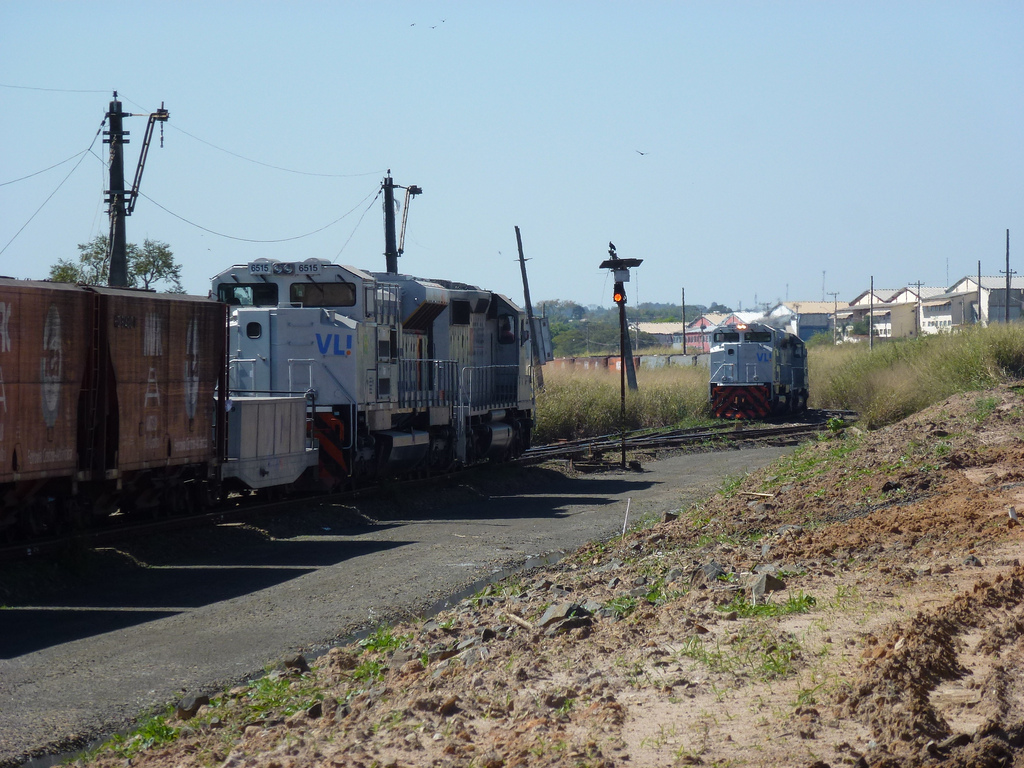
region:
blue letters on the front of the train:
[310, 325, 353, 360]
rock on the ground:
[510, 578, 612, 656]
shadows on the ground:
[124, 544, 309, 598]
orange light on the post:
[608, 282, 625, 317]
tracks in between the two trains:
[614, 417, 726, 450]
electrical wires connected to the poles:
[84, 79, 424, 247]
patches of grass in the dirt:
[731, 591, 824, 637]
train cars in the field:
[642, 350, 706, 373]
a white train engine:
[214, 261, 531, 493]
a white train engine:
[708, 321, 795, 419]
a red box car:
[5, 277, 220, 537]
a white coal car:
[223, 393, 318, 496]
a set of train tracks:
[495, 406, 846, 468]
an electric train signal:
[597, 241, 640, 470]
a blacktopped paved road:
[0, 441, 808, 759]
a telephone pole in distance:
[103, 92, 133, 280]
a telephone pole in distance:
[379, 171, 403, 276]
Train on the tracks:
[694, 293, 813, 423]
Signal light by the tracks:
[601, 243, 649, 472]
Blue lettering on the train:
[298, 322, 363, 364]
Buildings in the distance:
[623, 268, 1020, 376]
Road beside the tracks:
[5, 423, 859, 765]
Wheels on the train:
[2, 459, 225, 546]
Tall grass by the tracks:
[531, 319, 1019, 444]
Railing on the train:
[392, 358, 528, 415]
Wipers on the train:
[220, 265, 354, 303]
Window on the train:
[283, 271, 364, 317]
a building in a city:
[885, 280, 949, 339]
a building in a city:
[851, 283, 896, 341]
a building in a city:
[719, 302, 764, 329]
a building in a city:
[689, 310, 724, 349]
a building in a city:
[626, 308, 687, 357]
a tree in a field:
[30, 212, 185, 288]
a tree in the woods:
[538, 285, 586, 366]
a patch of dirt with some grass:
[259, 669, 389, 765]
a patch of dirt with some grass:
[379, 648, 520, 766]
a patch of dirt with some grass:
[503, 647, 634, 766]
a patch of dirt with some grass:
[623, 642, 742, 766]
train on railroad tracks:
[1, 243, 556, 531]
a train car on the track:
[400, 215, 557, 533]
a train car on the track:
[55, 279, 414, 659]